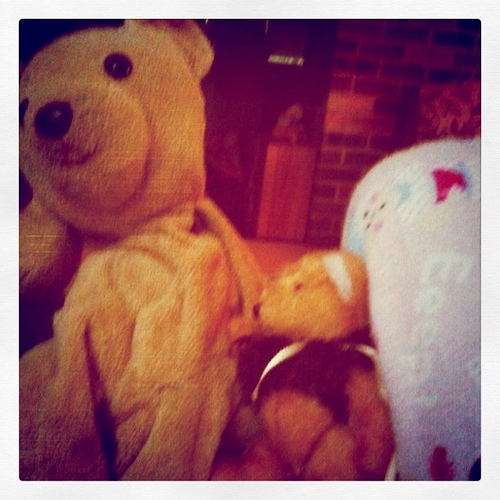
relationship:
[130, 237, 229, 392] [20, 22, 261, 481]
arm of teddy bear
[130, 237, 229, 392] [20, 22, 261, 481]
arm of a teddy bear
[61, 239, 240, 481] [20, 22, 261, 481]
body of teddy bear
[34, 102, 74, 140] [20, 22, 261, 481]
nose of a teddy bear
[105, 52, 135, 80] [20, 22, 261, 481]
eye of teddy bear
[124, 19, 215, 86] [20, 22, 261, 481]
ear of teddy bear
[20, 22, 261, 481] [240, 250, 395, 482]
teddy bear to left of cub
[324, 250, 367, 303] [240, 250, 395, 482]
ear of cub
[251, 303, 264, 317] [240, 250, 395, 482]
nose of a cub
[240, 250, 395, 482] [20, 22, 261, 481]
cub next to teddy bear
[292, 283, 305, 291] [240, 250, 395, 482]
eye of cub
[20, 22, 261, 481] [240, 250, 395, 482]
teddy bear next to cub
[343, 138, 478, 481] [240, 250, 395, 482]
cloth by cub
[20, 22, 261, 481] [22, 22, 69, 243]
teddy bear on right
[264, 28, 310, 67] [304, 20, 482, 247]
sign by wall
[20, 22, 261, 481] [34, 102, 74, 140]
teddy bear has a nose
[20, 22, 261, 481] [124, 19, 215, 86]
teddy bear has an ear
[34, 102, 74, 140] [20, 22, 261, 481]
nose of teddy bear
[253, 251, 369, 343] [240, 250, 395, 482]
head of a cub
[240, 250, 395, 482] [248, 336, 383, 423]
cub wearing a shirt